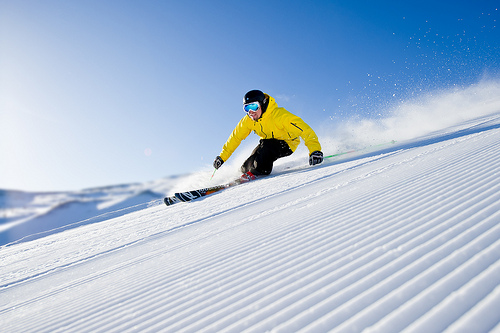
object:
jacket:
[217, 96, 321, 162]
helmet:
[241, 89, 267, 114]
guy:
[211, 89, 323, 182]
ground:
[0, 110, 499, 332]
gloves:
[306, 149, 324, 166]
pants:
[239, 138, 292, 178]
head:
[241, 89, 270, 121]